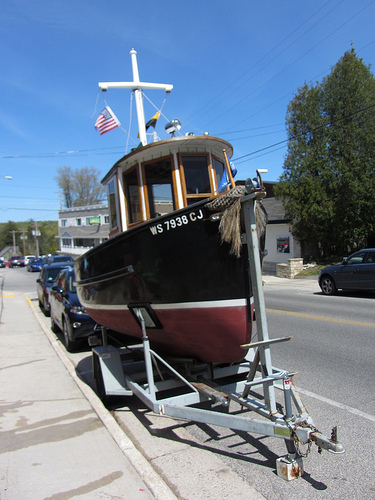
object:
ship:
[72, 45, 268, 363]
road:
[289, 293, 374, 499]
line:
[266, 306, 374, 328]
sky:
[0, 0, 374, 221]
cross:
[98, 46, 173, 149]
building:
[55, 202, 109, 254]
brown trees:
[52, 160, 99, 209]